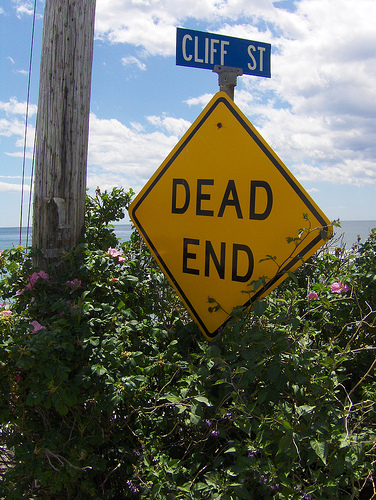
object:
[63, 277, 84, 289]
flowers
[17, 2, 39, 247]
pole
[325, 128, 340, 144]
ground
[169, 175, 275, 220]
letters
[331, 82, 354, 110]
ground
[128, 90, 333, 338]
border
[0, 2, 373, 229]
blue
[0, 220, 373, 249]
water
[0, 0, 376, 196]
clouds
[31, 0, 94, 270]
pole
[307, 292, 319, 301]
flowers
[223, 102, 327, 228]
black border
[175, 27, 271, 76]
blue sign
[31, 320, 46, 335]
flowers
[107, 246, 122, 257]
flowers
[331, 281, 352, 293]
flowers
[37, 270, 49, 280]
flowers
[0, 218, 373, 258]
blue ocean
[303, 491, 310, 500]
flowers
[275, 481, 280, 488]
flowers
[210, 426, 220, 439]
flowers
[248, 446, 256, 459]
flowers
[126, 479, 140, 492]
flowers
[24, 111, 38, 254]
wire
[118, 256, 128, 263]
pink flower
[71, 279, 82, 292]
pink flower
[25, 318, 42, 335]
pink flower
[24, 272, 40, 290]
pink flower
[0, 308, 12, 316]
pink flower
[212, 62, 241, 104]
pole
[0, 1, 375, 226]
blue sky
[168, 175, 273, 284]
dead end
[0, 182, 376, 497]
bush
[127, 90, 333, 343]
sign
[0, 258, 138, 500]
shadow